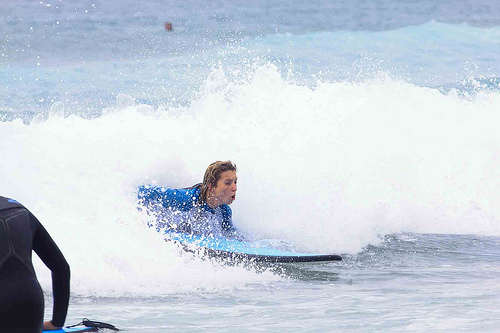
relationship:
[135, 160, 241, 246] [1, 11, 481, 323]
surfer in water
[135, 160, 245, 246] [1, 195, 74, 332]
surfer wearing black suit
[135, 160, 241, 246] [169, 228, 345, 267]
surfer laying on surfboard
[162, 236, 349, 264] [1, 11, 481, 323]
surf board on water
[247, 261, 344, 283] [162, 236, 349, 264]
shadow of surf board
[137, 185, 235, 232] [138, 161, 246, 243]
blue shirt of woman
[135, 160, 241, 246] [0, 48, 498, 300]
surfer trying to surf wave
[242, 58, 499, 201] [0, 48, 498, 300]
spray of wave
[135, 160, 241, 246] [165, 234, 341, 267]
surfer on surfboard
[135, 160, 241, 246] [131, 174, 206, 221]
surfer wearing shirt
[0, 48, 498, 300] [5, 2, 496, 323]
wave in ocean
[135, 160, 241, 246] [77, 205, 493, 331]
surfer in ocean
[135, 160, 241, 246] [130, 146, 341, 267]
surfer on surfboard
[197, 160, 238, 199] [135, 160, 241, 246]
hair on surfer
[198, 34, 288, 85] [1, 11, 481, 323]
splashes on water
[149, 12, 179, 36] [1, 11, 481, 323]
object in water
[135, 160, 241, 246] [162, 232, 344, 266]
surfer on surf board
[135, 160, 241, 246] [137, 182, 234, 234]
surfer wearing suit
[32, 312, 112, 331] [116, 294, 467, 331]
board on water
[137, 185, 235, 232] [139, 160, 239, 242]
blue shirt on person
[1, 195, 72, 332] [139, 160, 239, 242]
black suit on person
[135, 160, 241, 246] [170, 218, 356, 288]
surfer on surfboard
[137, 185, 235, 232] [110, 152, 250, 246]
blue shirt on woman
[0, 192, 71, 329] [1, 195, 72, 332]
person in black suit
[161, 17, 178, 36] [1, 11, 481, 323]
person in water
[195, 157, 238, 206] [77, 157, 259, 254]
hair on surfer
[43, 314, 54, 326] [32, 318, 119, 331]
hand on board